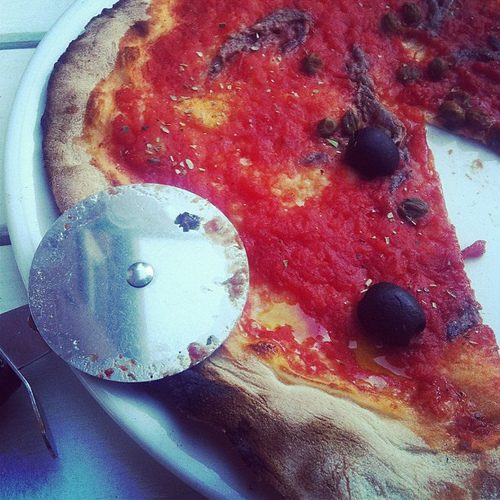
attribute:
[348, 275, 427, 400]
olive — black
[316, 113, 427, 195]
marks — burnt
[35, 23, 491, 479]
pita — cheese